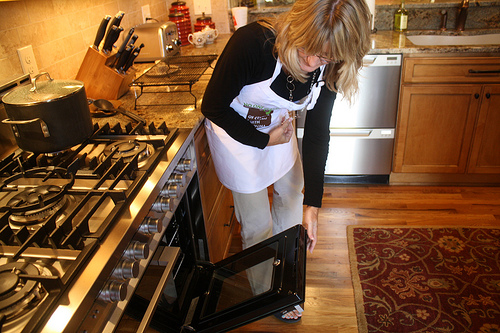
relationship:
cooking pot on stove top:
[0, 70, 94, 153] [0, 120, 178, 332]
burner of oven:
[0, 265, 58, 326] [0, 120, 309, 330]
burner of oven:
[110, 135, 162, 186] [0, 120, 309, 330]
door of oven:
[202, 241, 312, 330] [5, 139, 203, 331]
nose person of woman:
[296, 54, 328, 71] [200, 0, 369, 321]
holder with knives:
[72, 41, 138, 105] [74, 5, 150, 100]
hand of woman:
[264, 110, 299, 149] [200, 0, 369, 321]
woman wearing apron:
[200, 0, 376, 321] [206, 57, 335, 197]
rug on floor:
[321, 191, 463, 331] [342, 218, 496, 331]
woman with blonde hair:
[200, 0, 376, 321] [302, 15, 375, 59]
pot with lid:
[2, 72, 94, 149] [20, 66, 70, 108]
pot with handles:
[2, 72, 94, 149] [0, 112, 51, 146]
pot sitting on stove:
[2, 72, 94, 149] [3, 122, 217, 331]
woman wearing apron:
[200, 0, 376, 321] [201, 24, 328, 193]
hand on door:
[283, 217, 326, 251] [202, 241, 312, 330]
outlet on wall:
[13, 34, 40, 81] [1, 2, 173, 92]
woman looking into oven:
[200, 0, 376, 321] [159, 178, 307, 317]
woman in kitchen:
[200, 0, 376, 321] [3, 2, 498, 329]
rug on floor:
[347, 224, 499, 332] [211, 186, 498, 331]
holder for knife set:
[72, 45, 133, 99] [90, 19, 141, 69]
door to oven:
[202, 241, 312, 330] [0, 120, 309, 330]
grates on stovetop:
[6, 113, 188, 331] [1, 97, 197, 332]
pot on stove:
[2, 72, 94, 149] [46, 107, 198, 259]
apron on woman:
[201, 24, 328, 193] [176, 0, 434, 262]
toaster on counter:
[131, 17, 179, 62] [82, 29, 237, 132]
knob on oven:
[121, 228, 171, 275] [90, 130, 311, 331]